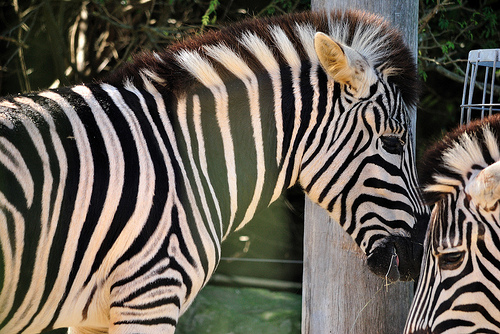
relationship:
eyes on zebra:
[372, 121, 417, 146] [19, 57, 430, 302]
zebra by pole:
[2, 5, 449, 312] [300, 0, 418, 332]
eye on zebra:
[436, 246, 466, 268] [400, 116, 500, 333]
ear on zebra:
[315, 32, 372, 99] [2, 5, 449, 312]